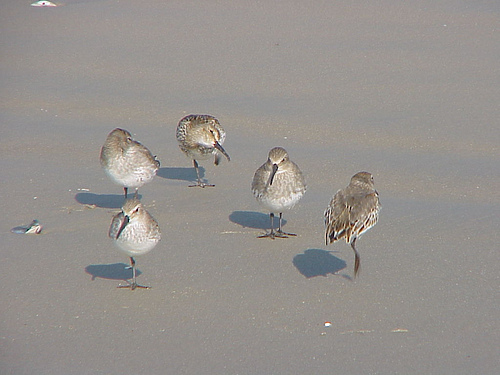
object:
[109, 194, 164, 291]
birds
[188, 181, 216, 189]
foot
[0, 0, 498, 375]
ground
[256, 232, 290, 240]
feet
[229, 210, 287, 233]
shadow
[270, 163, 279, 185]
beak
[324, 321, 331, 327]
white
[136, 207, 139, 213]
eye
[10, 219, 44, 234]
feather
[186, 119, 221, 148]
head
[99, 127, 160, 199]
sandpipers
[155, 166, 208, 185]
shadows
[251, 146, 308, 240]
bird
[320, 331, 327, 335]
stone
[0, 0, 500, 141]
sand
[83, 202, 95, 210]
tracks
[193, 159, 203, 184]
leg